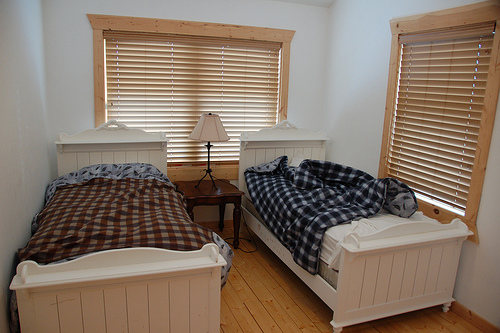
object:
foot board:
[327, 217, 473, 333]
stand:
[232, 205, 242, 251]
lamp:
[187, 113, 230, 194]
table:
[170, 179, 247, 249]